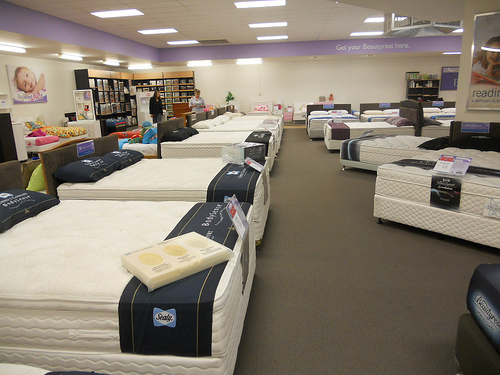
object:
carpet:
[248, 126, 491, 373]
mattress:
[0, 108, 281, 357]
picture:
[4, 62, 49, 104]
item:
[98, 101, 109, 116]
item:
[98, 87, 108, 102]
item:
[116, 102, 123, 112]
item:
[88, 77, 96, 87]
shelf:
[75, 65, 193, 142]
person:
[150, 90, 165, 125]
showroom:
[2, 1, 499, 373]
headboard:
[37, 131, 121, 196]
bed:
[32, 134, 271, 250]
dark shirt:
[149, 95, 163, 115]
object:
[118, 230, 236, 291]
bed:
[369, 154, 500, 251]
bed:
[340, 129, 500, 180]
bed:
[323, 118, 456, 152]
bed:
[306, 103, 362, 141]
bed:
[360, 101, 408, 131]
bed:
[422, 100, 460, 127]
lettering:
[336, 43, 410, 51]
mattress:
[311, 97, 500, 250]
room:
[0, 21, 500, 364]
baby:
[11, 67, 48, 102]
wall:
[0, 0, 500, 167]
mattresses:
[4, 129, 258, 364]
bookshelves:
[73, 68, 197, 131]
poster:
[439, 34, 500, 115]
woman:
[190, 89, 207, 113]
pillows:
[161, 124, 198, 142]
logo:
[150, 306, 180, 327]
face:
[16, 68, 36, 92]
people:
[150, 88, 205, 123]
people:
[188, 88, 206, 112]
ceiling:
[0, 0, 499, 49]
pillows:
[50, 148, 145, 184]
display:
[73, 69, 196, 127]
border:
[326, 42, 411, 52]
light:
[93, 9, 142, 20]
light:
[135, 28, 181, 35]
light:
[165, 39, 200, 45]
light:
[256, 35, 288, 41]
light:
[363, 16, 408, 23]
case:
[72, 68, 195, 134]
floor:
[254, 117, 499, 359]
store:
[0, 0, 500, 365]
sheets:
[0, 200, 219, 360]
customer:
[188, 88, 206, 114]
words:
[153, 314, 175, 322]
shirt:
[188, 95, 206, 111]